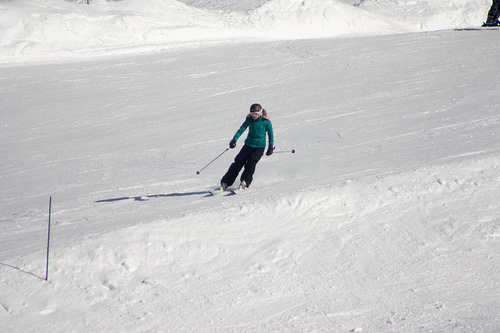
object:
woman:
[220, 103, 275, 190]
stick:
[42, 195, 52, 281]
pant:
[220, 143, 265, 189]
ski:
[208, 182, 248, 196]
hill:
[0, 0, 262, 69]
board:
[229, 182, 248, 194]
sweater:
[231, 114, 274, 148]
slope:
[375, 49, 500, 146]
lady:
[220, 103, 276, 190]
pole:
[195, 147, 230, 175]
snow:
[0, 0, 499, 333]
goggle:
[250, 112, 261, 117]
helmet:
[249, 103, 262, 114]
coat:
[229, 114, 274, 156]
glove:
[229, 139, 236, 148]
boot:
[208, 180, 249, 196]